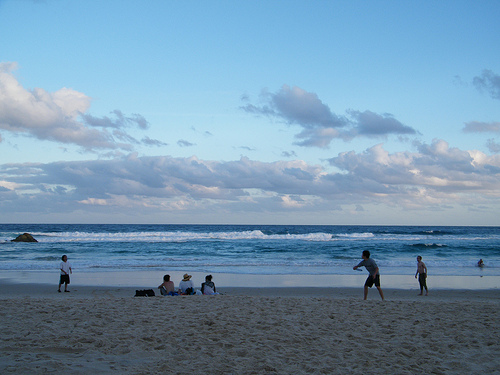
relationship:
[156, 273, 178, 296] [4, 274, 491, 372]
person on beach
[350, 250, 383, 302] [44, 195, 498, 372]
man on beach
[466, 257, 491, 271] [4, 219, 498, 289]
person in water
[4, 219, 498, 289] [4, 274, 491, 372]
water near beach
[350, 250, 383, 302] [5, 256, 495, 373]
man on beach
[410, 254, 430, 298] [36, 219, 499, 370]
man on beach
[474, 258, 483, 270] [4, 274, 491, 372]
person swimming near beach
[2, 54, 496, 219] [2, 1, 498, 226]
clouds in sky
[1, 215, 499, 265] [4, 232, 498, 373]
waves crashing on beach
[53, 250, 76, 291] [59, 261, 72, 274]
man wearing shirt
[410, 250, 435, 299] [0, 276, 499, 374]
man standing on beach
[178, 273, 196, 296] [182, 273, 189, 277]
person wears hat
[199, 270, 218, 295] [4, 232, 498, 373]
person on beach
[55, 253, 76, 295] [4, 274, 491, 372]
man on beach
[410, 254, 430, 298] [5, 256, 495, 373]
man on beach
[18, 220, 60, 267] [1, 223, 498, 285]
large rocks in water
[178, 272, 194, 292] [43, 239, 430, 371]
person on beach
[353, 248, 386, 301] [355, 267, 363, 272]
man holding frisbee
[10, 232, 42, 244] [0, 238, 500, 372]
large rocks next to shore